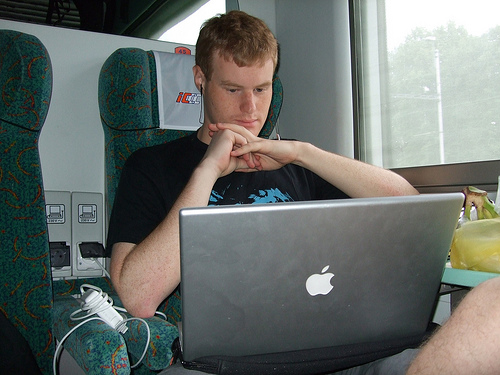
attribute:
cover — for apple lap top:
[169, 138, 438, 373]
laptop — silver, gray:
[176, 190, 466, 361]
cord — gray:
[50, 282, 166, 372]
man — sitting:
[100, 9, 499, 372]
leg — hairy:
[400, 273, 485, 373]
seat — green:
[1, 28, 134, 373]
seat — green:
[93, 40, 285, 371]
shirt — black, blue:
[102, 126, 351, 256]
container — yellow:
[450, 212, 482, 274]